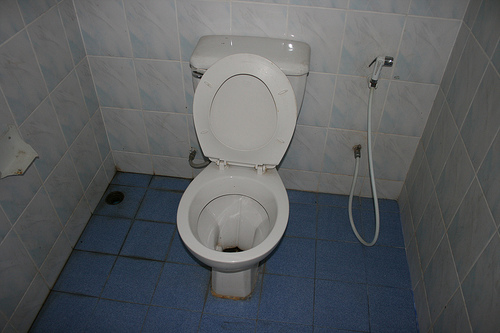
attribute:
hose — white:
[340, 50, 398, 250]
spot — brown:
[106, 167, 145, 206]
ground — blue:
[361, 144, 380, 191]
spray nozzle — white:
[366, 56, 393, 86]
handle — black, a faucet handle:
[361, 48, 404, 99]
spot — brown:
[206, 224, 247, 305]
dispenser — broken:
[1, 133, 47, 206]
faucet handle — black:
[365, 50, 392, 94]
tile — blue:
[55, 246, 116, 298]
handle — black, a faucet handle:
[191, 69, 205, 82]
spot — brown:
[350, 142, 363, 159]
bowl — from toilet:
[205, 200, 257, 243]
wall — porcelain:
[409, 95, 466, 225]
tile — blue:
[72, 212, 134, 257]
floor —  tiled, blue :
[25, 165, 417, 331]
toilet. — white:
[114, 44, 389, 323]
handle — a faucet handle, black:
[358, 50, 412, 170]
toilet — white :
[168, 39, 319, 271]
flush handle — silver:
[182, 59, 202, 83]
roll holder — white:
[9, 119, 76, 191]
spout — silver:
[374, 48, 404, 79]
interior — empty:
[203, 184, 303, 274]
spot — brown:
[77, 160, 120, 225]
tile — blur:
[321, 252, 395, 328]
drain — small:
[99, 188, 128, 208]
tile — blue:
[38, 170, 401, 331]